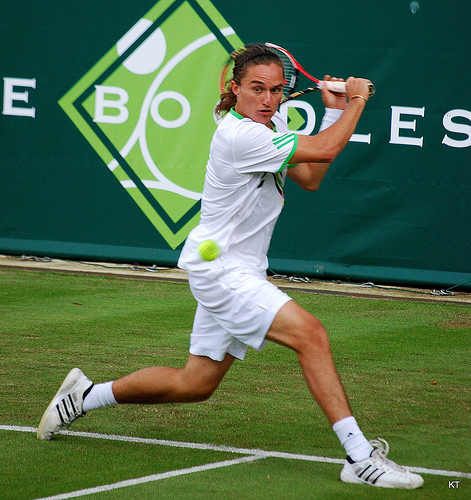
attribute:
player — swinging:
[159, 37, 383, 394]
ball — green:
[192, 235, 226, 266]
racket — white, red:
[219, 36, 384, 119]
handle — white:
[314, 77, 384, 100]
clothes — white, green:
[182, 108, 306, 342]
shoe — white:
[343, 440, 427, 495]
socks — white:
[81, 375, 122, 417]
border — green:
[280, 130, 303, 179]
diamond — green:
[69, 3, 267, 233]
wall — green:
[340, 18, 447, 78]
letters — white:
[385, 92, 468, 158]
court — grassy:
[8, 262, 462, 496]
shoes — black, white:
[329, 441, 434, 496]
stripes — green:
[52, 394, 84, 429]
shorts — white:
[181, 239, 292, 370]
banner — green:
[5, 25, 166, 271]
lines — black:
[358, 459, 395, 494]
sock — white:
[329, 410, 384, 453]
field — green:
[39, 272, 191, 358]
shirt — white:
[209, 113, 285, 272]